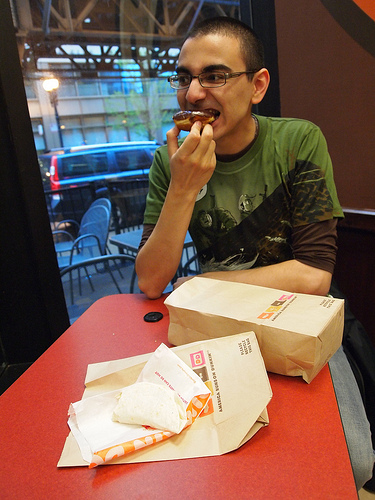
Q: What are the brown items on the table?
A: Paper bags.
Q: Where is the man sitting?
A: At an orange table.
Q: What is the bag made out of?
A: Paper.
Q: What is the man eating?
A: Doughnut.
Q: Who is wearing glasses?
A: Man eating doughnut.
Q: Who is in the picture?
A: A man.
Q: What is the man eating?
A: A doughnut.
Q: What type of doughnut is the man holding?
A: Chocolate.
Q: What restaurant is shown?
A: Dunkin Donuts.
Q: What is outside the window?
A: Chairs.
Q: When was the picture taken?
A: Early morning.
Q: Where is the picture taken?
A: Restaurant.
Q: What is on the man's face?
A: Glasses.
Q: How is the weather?
A: Clear.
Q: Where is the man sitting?
A: A table.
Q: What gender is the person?
A: Male.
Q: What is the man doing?
A: Eating.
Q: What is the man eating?
A: Doughnut.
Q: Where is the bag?
A: On the table.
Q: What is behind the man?
A: Window.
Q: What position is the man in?
A: Sitting.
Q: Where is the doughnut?
A: In the man's mouth.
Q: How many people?
A: 1.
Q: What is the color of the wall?
A: Brown.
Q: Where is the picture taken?
A: In the cafeteria.